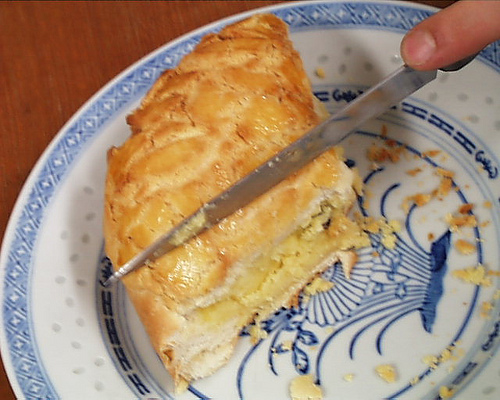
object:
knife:
[100, 41, 483, 290]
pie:
[122, 16, 372, 384]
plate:
[0, 0, 500, 400]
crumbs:
[367, 139, 484, 270]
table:
[2, 3, 96, 96]